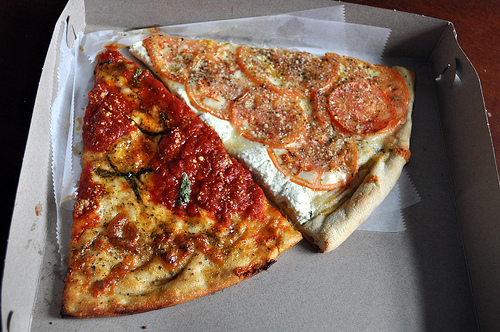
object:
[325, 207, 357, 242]
crust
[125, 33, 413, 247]
pizza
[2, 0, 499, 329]
box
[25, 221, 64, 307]
splat of grease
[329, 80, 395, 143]
tomato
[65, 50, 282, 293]
cheese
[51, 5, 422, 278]
parchment paper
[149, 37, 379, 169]
seasoning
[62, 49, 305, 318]
pizza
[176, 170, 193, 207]
piece of herb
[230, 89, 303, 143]
pepperoni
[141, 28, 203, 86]
slice of pepperoni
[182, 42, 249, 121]
slice of pepperoni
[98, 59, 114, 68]
spot